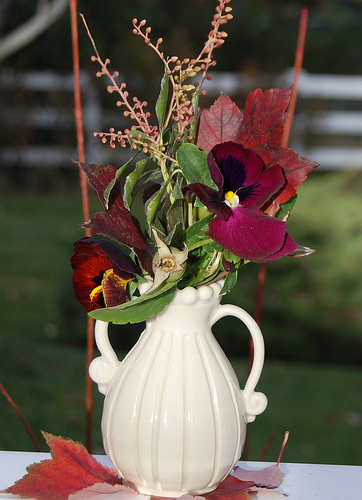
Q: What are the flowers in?
A: Vase.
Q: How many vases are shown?
A: One.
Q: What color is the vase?
A: White.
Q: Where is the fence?
A: Background.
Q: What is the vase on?
A: Leaves.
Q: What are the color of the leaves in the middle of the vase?
A: Green.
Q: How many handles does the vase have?
A: Two.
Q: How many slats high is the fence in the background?
A: Three.